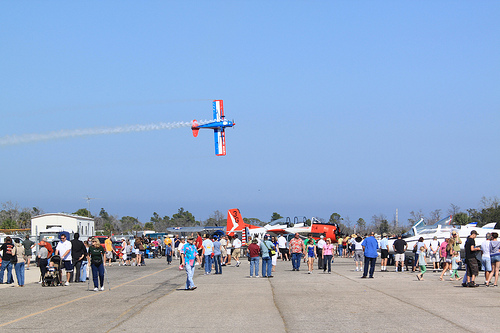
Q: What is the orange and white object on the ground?
A: A plane.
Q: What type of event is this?
A: An air show.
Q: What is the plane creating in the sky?
A: A smoke trial.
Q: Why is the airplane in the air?
A: It is flying.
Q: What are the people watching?
A: An air show.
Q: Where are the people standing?
A: At an airport.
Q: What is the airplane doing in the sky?
A: Flying.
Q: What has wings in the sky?
A: Plane.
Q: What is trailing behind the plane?
A: White exhaust.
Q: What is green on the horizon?
A: Trees.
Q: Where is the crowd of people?
A: Air show tarmac.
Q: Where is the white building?
A: Left of crowd.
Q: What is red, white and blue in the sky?
A: Plane wings.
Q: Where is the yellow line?
A: Tarmac surface.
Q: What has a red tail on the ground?
A: Plane in the back middle.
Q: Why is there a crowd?
A: Look at planes.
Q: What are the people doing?
A: Watching the planes.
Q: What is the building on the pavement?
A: Trailer.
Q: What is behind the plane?
A: Smoke.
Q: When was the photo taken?
A: Daytime.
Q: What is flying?
A: A plane.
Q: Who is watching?
A: Several people.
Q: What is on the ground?
A: Planes.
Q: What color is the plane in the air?
A: Red, white and blue.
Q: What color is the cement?
A: Gray.